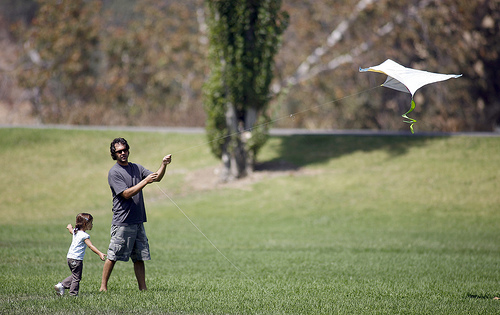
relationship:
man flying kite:
[98, 136, 173, 301] [358, 58, 462, 134]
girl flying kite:
[54, 214, 106, 294] [358, 58, 462, 134]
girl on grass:
[52, 212, 107, 297] [2, 130, 498, 312]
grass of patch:
[2, 130, 498, 312] [249, 278, 323, 312]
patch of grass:
[0, 125, 499, 314] [2, 130, 498, 312]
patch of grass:
[374, 278, 416, 303] [2, 130, 498, 312]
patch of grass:
[0, 125, 499, 314] [351, 214, 478, 276]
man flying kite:
[98, 136, 173, 301] [354, 57, 469, 130]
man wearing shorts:
[98, 138, 175, 294] [103, 216, 152, 261]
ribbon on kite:
[400, 96, 418, 135] [360, 58, 462, 95]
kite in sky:
[358, 58, 462, 134] [2, 3, 498, 145]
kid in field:
[47, 209, 100, 309] [3, 127, 498, 312]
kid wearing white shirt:
[53, 211, 108, 298] [68, 227, 87, 260]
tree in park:
[179, 13, 301, 211] [2, 120, 498, 309]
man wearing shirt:
[98, 138, 175, 294] [110, 140, 135, 222]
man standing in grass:
[98, 138, 175, 294] [227, 271, 284, 308]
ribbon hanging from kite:
[394, 96, 420, 133] [346, 44, 469, 141]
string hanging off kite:
[169, 75, 363, 164] [350, 42, 430, 127]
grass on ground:
[2, 130, 499, 315] [211, 176, 430, 288]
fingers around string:
[161, 153, 175, 163] [168, 77, 398, 160]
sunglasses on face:
[110, 147, 130, 153] [106, 141, 131, 160]